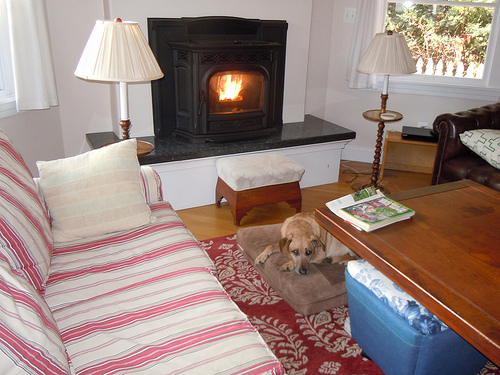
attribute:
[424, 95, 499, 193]
couch — dark brown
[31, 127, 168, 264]
pillow — white, seat pillow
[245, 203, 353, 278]
dog — brown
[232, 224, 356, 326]
cushion — brown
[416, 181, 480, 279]
table — wooden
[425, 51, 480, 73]
fence — white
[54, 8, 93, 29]
wall — white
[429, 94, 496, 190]
sofa — brown, leather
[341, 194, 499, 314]
table — wooden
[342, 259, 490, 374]
basket — light blue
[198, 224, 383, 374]
carpet — red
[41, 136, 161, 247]
pink pillow — light pink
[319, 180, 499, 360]
table — brown 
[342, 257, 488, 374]
container — blue, under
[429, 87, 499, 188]
couch — brown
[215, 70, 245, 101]
fire — yellow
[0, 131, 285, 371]
couch — pink, white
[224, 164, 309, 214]
stool — brown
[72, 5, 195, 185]
lamp — beside